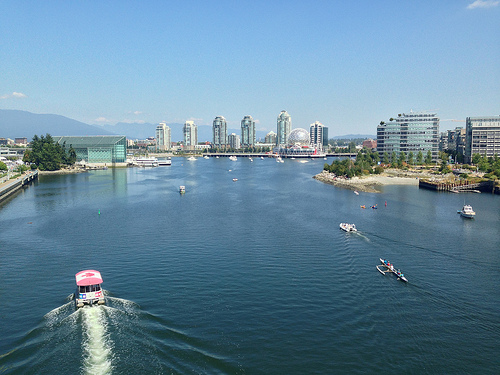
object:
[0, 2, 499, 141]
sky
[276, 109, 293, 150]
building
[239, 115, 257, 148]
building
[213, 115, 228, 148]
building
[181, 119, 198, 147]
building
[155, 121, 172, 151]
building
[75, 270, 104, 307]
boat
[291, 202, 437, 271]
water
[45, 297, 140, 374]
water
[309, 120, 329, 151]
building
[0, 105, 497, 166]
background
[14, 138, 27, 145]
building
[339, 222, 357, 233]
boat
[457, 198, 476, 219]
boat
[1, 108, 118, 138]
mountain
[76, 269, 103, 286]
roof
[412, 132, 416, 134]
window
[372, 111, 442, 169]
building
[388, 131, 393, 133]
window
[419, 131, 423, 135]
window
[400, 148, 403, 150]
window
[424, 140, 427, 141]
window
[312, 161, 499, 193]
shore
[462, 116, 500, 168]
building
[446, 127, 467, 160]
building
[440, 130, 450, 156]
building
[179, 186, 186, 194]
boat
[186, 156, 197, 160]
boat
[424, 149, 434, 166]
tree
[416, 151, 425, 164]
tree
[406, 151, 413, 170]
tree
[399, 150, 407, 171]
tree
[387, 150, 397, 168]
tree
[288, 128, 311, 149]
building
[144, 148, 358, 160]
shore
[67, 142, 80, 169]
tree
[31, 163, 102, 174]
land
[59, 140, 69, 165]
tree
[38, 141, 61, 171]
tree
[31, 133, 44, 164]
tree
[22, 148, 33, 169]
tree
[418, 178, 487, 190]
deck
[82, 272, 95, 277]
symbol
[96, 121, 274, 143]
mountain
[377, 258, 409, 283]
row boat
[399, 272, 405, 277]
people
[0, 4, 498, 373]
image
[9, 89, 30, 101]
cloud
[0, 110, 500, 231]
city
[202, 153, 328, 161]
dock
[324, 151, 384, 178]
shrubbery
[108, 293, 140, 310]
ripple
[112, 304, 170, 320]
ripple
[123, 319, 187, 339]
ripple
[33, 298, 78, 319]
ripple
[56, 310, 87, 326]
ripple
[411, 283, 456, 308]
ripples